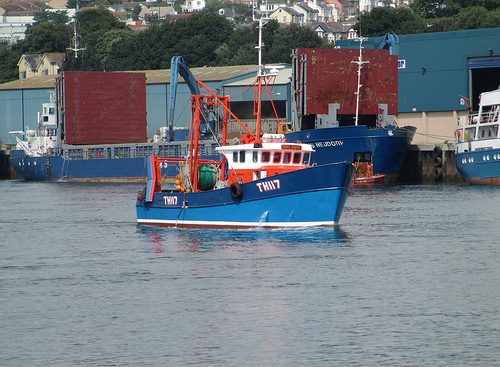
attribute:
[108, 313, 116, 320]
spot — black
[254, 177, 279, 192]
numbers — red, white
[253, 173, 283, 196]
numbers — red, white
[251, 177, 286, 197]
numbers — white, red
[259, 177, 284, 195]
numbers — white, red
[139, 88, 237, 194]
equipment — white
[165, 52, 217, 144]
crain — blue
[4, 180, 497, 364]
water — calm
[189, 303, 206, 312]
spot — black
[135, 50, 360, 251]
boat — large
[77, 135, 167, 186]
wall — blue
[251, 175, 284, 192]
numbers — red, white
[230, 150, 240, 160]
window — small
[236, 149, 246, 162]
window — small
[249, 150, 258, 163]
window — small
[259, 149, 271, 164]
window — small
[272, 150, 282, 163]
window — small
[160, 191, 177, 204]
numbers — white, red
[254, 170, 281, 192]
numbers — red, white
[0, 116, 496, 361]
lake — large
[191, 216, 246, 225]
color — white